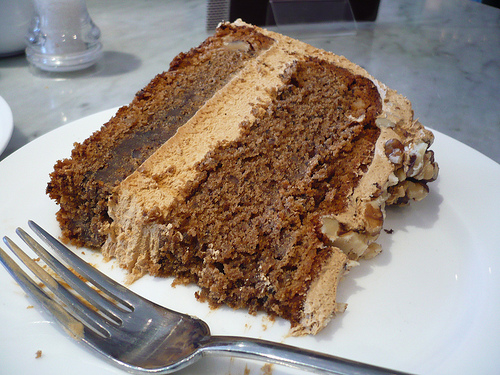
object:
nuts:
[349, 116, 365, 125]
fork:
[0, 218, 411, 374]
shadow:
[408, 205, 434, 223]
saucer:
[0, 99, 499, 375]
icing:
[286, 59, 295, 70]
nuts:
[385, 139, 404, 164]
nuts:
[320, 219, 339, 241]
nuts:
[363, 205, 384, 237]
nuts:
[423, 164, 433, 180]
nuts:
[409, 184, 425, 199]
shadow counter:
[83, 70, 93, 75]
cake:
[46, 17, 439, 336]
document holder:
[266, 0, 358, 37]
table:
[0, 0, 499, 375]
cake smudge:
[6, 245, 54, 279]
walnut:
[346, 234, 361, 250]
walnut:
[391, 151, 402, 160]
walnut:
[417, 144, 424, 153]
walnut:
[406, 186, 424, 197]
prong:
[1, 221, 134, 341]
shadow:
[101, 55, 136, 72]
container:
[22, 1, 102, 73]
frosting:
[388, 137, 430, 190]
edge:
[2, 95, 15, 150]